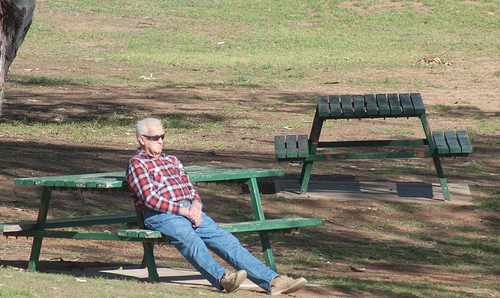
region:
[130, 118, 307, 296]
old man sitting on public bench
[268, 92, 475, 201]
green, empty bench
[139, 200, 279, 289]
blue jeans being worn by man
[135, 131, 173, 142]
sunglasses protecting man's eyes from sun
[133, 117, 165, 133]
white hair indicating this person has aged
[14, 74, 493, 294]
shadow from large tree not shown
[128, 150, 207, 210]
flannel button up shirt being worn by man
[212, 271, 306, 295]
shoes protecting man's feet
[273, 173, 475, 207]
concerete slab for table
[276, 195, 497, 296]
ground with patches of grass missing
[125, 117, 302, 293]
An old man sitting on a green bench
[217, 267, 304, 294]
A brown pair of shoes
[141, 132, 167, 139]
A pair of dark sunglasses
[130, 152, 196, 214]
A red plaid shirt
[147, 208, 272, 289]
A pair of blue jeans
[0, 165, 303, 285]
A green picnic bench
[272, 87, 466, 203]
A second green picnic bench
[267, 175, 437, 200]
Shadows under the picnic bench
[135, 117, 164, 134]
A head of white hair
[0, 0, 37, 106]
The edge of a tree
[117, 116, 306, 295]
the man is sitting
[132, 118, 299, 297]
the man on the bench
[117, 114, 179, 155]
the man wearing sunglasses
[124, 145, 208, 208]
the man wearing a plaid shirt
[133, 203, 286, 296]
the man wearing jeans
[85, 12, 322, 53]
the grass on the ground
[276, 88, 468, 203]
the empty picnic table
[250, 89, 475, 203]
the picnic table is green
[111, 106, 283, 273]
the man is old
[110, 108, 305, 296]
the man is resting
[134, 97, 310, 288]
man sitting on a green picnic bench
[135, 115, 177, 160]
older man wearing black sunglasses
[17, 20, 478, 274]
photograph taken at the park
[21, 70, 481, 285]
two wooden green picnic tables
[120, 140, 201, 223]
man wearing a plaid button down shirt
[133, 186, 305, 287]
man wearing blue jeans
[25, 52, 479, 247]
shadow of tree on ground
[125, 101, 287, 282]
man sitting with hands folded in lap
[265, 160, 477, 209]
cement under picnic table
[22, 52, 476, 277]
picnic tables with green paint chipping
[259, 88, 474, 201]
a green picnic table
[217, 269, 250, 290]
the shoe of a man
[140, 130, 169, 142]
dark black sunglasses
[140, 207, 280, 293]
a man's blue jean pants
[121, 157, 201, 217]
a man's red and white shirt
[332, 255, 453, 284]
a section of brown dirt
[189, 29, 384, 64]
a section of green grass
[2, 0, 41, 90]
part of a tree branch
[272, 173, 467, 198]
a piece of concrete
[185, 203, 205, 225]
the hand of a man